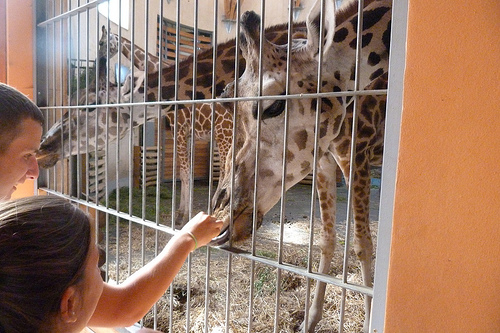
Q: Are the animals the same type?
A: Yes, all the animals are giraffes.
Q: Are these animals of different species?
A: No, all the animals are giraffes.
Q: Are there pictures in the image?
A: No, there are no pictures.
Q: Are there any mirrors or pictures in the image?
A: No, there are no pictures or mirrors.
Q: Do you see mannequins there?
A: No, there are no mannequins.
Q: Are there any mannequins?
A: No, there are no mannequins.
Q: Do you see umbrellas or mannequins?
A: No, there are no mannequins or umbrellas.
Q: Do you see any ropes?
A: No, there are no ropes.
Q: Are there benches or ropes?
A: No, there are no ropes or benches.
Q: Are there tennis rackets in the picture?
A: No, there are no tennis rackets.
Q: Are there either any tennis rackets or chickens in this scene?
A: No, there are no tennis rackets or chickens.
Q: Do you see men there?
A: No, there are no men.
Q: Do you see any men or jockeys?
A: No, there are no men or jockeys.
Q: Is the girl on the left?
A: Yes, the girl is on the left of the image.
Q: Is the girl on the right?
A: No, the girl is on the left of the image.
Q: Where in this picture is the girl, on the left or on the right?
A: The girl is on the left of the image.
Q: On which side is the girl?
A: The girl is on the left of the image.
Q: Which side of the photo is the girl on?
A: The girl is on the left of the image.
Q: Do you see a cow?
A: No, there are no cows.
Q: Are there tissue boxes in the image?
A: No, there are no tissue boxes.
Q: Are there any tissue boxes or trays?
A: No, there are no tissue boxes or trays.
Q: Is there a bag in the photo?
A: No, there are no bags.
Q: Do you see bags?
A: No, there are no bags.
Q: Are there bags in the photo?
A: No, there are no bags.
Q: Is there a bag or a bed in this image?
A: No, there are no bags or beds.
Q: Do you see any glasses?
A: No, there are no glasses.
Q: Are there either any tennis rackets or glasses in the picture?
A: No, there are no glasses or tennis rackets.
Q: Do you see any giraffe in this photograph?
A: Yes, there is a giraffe.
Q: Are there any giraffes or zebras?
A: Yes, there is a giraffe.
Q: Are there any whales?
A: No, there are no whales.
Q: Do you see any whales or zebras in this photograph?
A: No, there are no whales or zebras.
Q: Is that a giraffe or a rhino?
A: That is a giraffe.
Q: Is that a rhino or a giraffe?
A: That is a giraffe.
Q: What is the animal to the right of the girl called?
A: The animal is a giraffe.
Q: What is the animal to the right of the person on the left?
A: The animal is a giraffe.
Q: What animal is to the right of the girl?
A: The animal is a giraffe.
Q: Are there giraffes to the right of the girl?
A: Yes, there is a giraffe to the right of the girl.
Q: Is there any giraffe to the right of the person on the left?
A: Yes, there is a giraffe to the right of the girl.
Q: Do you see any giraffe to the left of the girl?
A: No, the giraffe is to the right of the girl.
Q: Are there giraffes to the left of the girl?
A: No, the giraffe is to the right of the girl.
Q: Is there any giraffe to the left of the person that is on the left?
A: No, the giraffe is to the right of the girl.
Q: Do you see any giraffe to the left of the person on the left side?
A: No, the giraffe is to the right of the girl.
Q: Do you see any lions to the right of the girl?
A: No, there is a giraffe to the right of the girl.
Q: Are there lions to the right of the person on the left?
A: No, there is a giraffe to the right of the girl.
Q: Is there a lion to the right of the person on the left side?
A: No, there is a giraffe to the right of the girl.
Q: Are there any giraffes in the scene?
A: Yes, there are giraffes.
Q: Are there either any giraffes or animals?
A: Yes, there are giraffes.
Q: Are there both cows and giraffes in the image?
A: No, there are giraffes but no cows.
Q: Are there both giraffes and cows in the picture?
A: No, there are giraffes but no cows.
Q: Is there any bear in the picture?
A: No, there are no bears.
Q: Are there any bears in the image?
A: No, there are no bears.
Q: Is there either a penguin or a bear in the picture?
A: No, there are no bears or penguins.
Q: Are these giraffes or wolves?
A: These are giraffes.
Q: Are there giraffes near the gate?
A: Yes, there are giraffes near the gate.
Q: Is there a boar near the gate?
A: No, there are giraffes near the gate.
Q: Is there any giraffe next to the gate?
A: Yes, there are giraffes next to the gate.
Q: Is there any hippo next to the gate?
A: No, there are giraffes next to the gate.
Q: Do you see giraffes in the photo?
A: Yes, there is a giraffe.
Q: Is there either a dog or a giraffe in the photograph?
A: Yes, there is a giraffe.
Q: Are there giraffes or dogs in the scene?
A: Yes, there is a giraffe.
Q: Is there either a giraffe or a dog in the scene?
A: Yes, there is a giraffe.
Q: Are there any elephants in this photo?
A: No, there are no elephants.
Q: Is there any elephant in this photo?
A: No, there are no elephants.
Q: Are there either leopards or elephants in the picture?
A: No, there are no elephants or leopards.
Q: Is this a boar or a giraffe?
A: This is a giraffe.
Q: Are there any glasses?
A: No, there are no glasses.